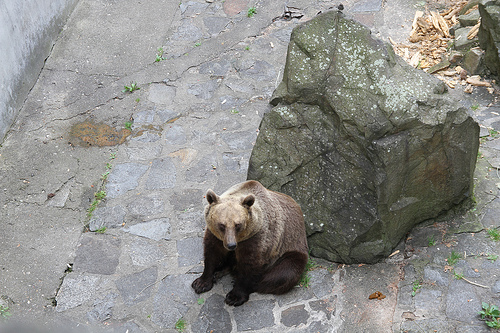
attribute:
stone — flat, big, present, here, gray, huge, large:
[262, 44, 432, 248]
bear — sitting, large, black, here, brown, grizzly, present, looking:
[189, 204, 303, 318]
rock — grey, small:
[380, 137, 448, 206]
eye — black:
[212, 212, 247, 240]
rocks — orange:
[338, 76, 440, 162]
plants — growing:
[440, 225, 498, 293]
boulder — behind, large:
[253, 19, 467, 259]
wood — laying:
[408, 7, 477, 78]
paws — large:
[186, 241, 260, 318]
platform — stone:
[53, 48, 217, 252]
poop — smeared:
[72, 89, 120, 140]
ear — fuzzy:
[228, 180, 271, 224]